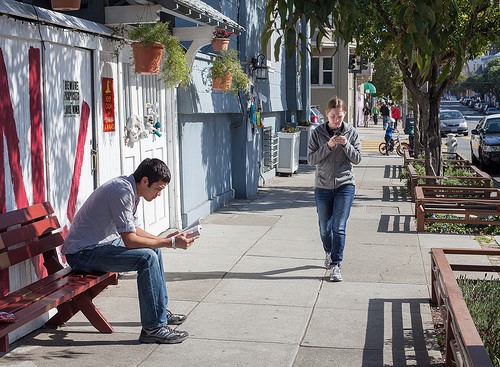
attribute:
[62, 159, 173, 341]
man — sitting, young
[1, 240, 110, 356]
bench — red, wooden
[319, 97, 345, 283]
woman — young, texting, walking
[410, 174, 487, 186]
fence — wood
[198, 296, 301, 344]
pavement — concrete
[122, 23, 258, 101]
plants — hanging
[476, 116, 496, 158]
car — black, white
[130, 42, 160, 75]
pot — hanging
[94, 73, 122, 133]
sign — red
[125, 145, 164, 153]
doors — white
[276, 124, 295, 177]
pot — gray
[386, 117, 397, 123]
helmet — blue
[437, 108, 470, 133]
car — parked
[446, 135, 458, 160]
hydrant — white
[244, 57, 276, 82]
light — hanging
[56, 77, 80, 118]
sign — white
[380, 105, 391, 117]
shirt — black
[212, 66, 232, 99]
pot — red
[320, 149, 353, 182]
shirt — gray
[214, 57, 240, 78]
leaves — green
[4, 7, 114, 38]
awning — blue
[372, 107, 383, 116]
shirt — gree